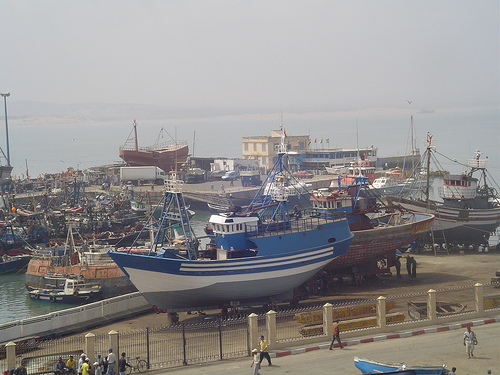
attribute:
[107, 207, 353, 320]
boats — elevated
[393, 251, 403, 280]
people — elevated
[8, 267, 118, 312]
gray barge — gray and tan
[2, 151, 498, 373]
dock — boat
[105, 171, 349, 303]
boats — large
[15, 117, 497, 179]
sea — muted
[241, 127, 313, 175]
building — boxy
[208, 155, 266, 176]
building — flat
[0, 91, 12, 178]
mast — tall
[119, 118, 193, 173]
ship — brown, being built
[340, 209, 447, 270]
boat — brown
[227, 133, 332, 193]
building — large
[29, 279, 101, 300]
boat — small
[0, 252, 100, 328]
water — green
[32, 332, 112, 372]
crowd — large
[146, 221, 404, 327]
dock — large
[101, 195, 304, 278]
boat — blue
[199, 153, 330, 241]
structures — metal